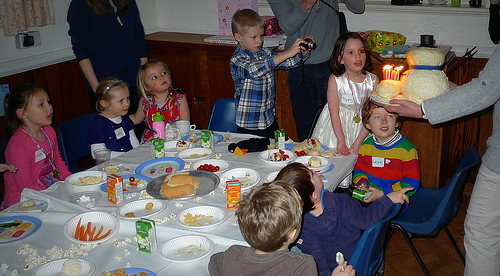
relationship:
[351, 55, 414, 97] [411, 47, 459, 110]
candles on cake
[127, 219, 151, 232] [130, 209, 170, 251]
box of juice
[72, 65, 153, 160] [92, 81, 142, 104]
girl has headband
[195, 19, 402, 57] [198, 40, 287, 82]
presents on counter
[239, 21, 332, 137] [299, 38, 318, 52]
boy taking camera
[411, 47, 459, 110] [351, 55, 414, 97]
cake with candles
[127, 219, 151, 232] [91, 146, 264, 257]
box on table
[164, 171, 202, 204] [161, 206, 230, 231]
buns on plate